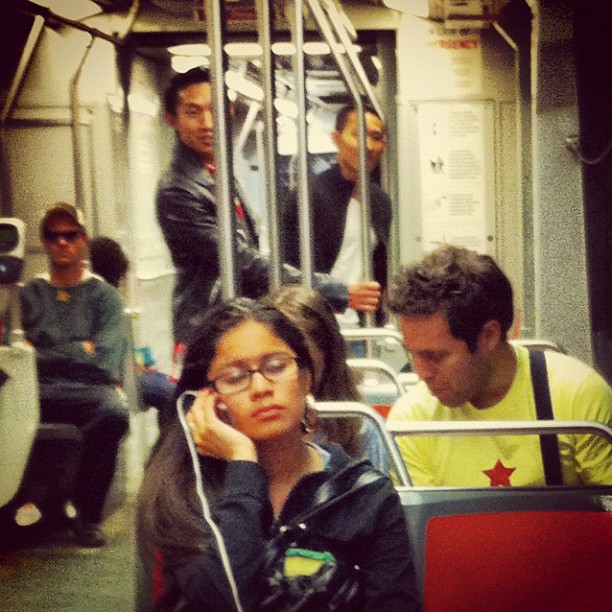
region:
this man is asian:
[162, 92, 235, 242]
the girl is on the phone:
[127, 296, 431, 607]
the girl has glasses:
[216, 357, 315, 416]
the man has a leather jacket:
[145, 144, 237, 299]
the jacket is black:
[131, 153, 272, 292]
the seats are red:
[417, 490, 584, 608]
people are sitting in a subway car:
[24, 205, 610, 591]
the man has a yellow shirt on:
[379, 246, 610, 486]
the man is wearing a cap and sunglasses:
[31, 195, 94, 298]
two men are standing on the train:
[151, 59, 387, 375]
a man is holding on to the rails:
[155, 68, 386, 350]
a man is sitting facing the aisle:
[91, 234, 180, 431]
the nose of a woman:
[230, 371, 278, 412]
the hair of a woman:
[138, 281, 346, 499]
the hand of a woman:
[164, 391, 265, 495]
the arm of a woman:
[143, 392, 298, 607]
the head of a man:
[395, 247, 540, 425]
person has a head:
[399, 251, 514, 404]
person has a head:
[200, 302, 313, 439]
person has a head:
[265, 287, 338, 399]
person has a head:
[37, 206, 89, 268]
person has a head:
[166, 69, 217, 153]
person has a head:
[332, 103, 387, 173]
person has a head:
[89, 235, 128, 289]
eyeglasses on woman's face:
[203, 299, 310, 437]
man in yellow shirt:
[390, 241, 609, 484]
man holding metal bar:
[158, 65, 382, 326]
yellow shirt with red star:
[389, 346, 610, 487]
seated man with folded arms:
[15, 200, 128, 541]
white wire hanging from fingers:
[173, 389, 241, 610]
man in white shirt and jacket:
[284, 107, 389, 327]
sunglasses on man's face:
[44, 214, 86, 266]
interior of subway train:
[2, 1, 609, 608]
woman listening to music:
[137, 294, 437, 610]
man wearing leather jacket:
[153, 63, 382, 337]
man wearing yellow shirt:
[363, 243, 607, 495]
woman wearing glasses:
[145, 297, 419, 609]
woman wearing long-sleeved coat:
[146, 298, 425, 610]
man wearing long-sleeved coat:
[276, 100, 400, 334]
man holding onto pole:
[153, 65, 382, 336]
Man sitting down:
[13, 201, 131, 548]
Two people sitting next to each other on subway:
[214, 245, 610, 495]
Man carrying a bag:
[375, 237, 610, 484]